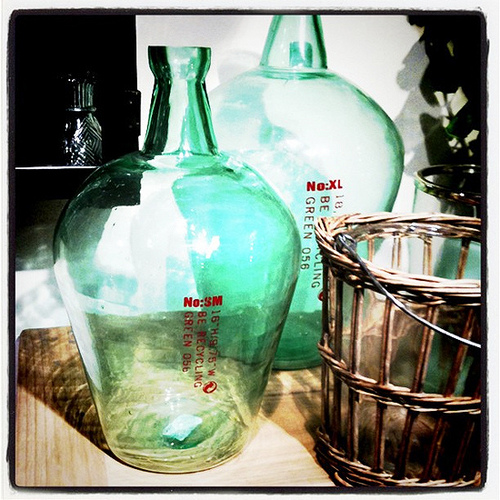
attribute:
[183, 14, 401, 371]
glass jar — tinted blue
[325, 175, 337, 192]
letter x — red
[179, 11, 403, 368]
jar — glass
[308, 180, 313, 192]
n — red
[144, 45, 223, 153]
neck — narrow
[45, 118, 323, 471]
glass — green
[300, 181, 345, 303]
print — red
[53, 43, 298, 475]
bottle — green tinted, wide, green, glass, small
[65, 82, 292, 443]
jar — glass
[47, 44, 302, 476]
jar — glass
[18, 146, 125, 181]
shelf — brown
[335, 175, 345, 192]
l — red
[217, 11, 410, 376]
jar — glassy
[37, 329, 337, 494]
table — wood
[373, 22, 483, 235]
plant — tall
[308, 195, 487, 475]
basket — woven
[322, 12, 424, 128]
wall — white, black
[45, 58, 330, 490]
glass — silver trimmed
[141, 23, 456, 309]
wall — white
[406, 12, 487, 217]
leaves — green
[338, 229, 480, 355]
handle — metal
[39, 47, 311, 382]
jar — green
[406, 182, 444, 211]
glass — metal rimmed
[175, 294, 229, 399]
print — red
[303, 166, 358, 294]
print — red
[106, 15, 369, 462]
bottles — green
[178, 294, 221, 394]
print — red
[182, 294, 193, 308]
letter n — red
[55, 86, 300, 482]
jar — glass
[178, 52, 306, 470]
tint — blue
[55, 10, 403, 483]
tint — blue